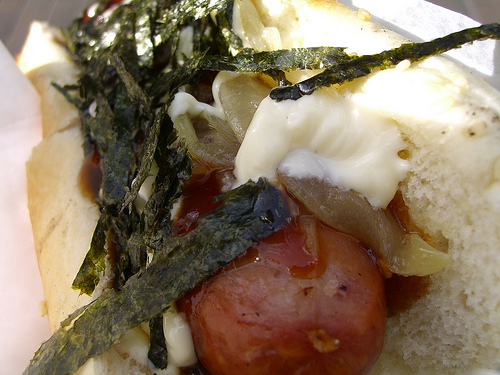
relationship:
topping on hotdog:
[21, 0, 500, 374] [188, 198, 388, 375]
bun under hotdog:
[15, 1, 500, 374] [188, 198, 388, 375]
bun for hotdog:
[15, 1, 500, 374] [188, 198, 388, 375]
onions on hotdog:
[169, 73, 449, 277] [188, 198, 388, 375]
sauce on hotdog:
[78, 147, 324, 318] [188, 198, 388, 375]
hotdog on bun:
[188, 198, 388, 375] [15, 1, 500, 374]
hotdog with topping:
[188, 198, 388, 375] [21, 0, 500, 374]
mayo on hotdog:
[233, 89, 409, 211] [188, 198, 388, 375]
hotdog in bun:
[188, 198, 388, 375] [15, 1, 500, 374]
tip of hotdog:
[308, 326, 339, 358] [188, 198, 388, 375]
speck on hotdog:
[340, 283, 348, 292] [188, 198, 388, 375]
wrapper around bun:
[1, 2, 500, 373] [15, 1, 500, 374]